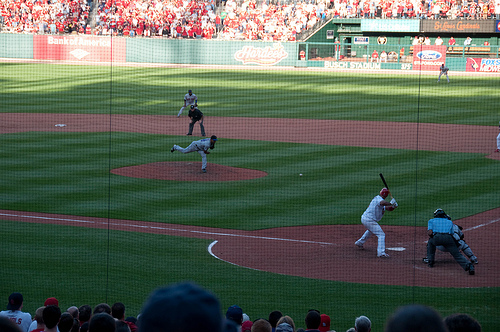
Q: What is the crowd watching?
A: Baseball game.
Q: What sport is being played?
A: Baseball.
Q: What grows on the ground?
A: Grass.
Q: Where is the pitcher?
A: On the dirt mound.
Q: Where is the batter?
A: Home plate.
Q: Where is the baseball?
A: In the air.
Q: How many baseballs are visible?
A: One.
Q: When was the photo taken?
A: Daytime.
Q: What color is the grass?
A: Green.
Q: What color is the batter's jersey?
A: White.